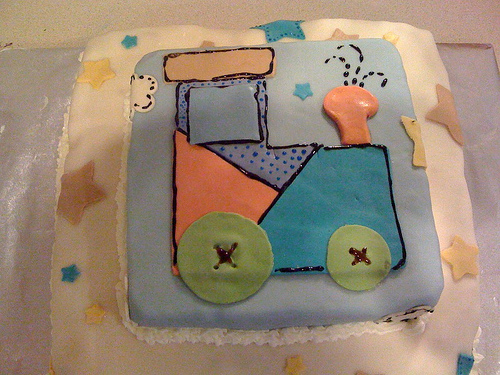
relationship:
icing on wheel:
[102, 35, 452, 343] [174, 208, 275, 307]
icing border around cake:
[116, 314, 427, 349] [0, 17, 498, 373]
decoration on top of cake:
[94, 147, 286, 337] [45, 15, 486, 374]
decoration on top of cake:
[126, 39, 448, 337] [0, 17, 498, 373]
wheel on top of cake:
[324, 222, 394, 293] [0, 17, 498, 373]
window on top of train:
[183, 87, 258, 142] [152, 34, 414, 312]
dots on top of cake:
[197, 141, 324, 193] [45, 15, 486, 374]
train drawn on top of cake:
[159, 46, 409, 308] [45, 15, 486, 374]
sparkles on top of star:
[253, 17, 311, 53] [252, 11, 327, 52]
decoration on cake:
[126, 39, 448, 337] [0, 17, 498, 373]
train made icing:
[159, 46, 409, 308] [64, 24, 464, 339]